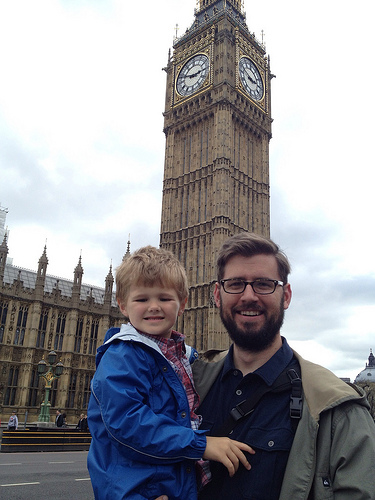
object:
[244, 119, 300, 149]
ground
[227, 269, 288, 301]
glasses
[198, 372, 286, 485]
blue shirt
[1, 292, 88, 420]
wall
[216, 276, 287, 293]
eyeglasses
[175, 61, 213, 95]
clock face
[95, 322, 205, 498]
blue jacket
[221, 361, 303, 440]
straps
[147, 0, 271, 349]
tower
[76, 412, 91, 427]
person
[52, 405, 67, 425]
person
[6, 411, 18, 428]
person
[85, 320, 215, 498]
coat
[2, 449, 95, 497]
road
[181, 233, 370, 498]
man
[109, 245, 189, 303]
blonde hair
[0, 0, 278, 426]
building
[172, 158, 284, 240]
wall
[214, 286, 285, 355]
beard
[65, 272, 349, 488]
foreground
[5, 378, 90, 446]
background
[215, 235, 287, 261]
hair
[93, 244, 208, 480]
boy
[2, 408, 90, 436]
people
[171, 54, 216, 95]
clock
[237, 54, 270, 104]
clock